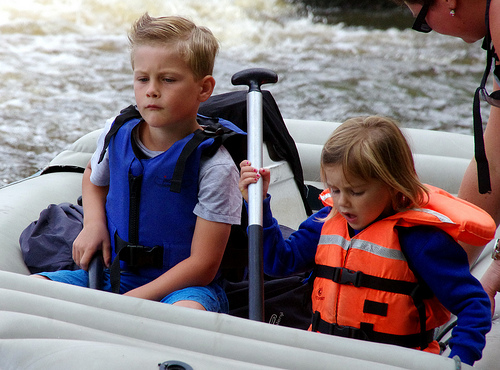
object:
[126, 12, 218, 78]
hair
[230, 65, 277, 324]
paddle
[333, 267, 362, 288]
clip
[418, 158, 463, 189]
ground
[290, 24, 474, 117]
waves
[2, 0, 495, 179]
river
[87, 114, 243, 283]
shirt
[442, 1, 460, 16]
ear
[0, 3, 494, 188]
water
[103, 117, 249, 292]
blue jacket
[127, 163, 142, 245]
zipper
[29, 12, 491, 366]
boy girl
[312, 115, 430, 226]
hair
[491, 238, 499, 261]
wristwatch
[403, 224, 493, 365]
blue sleeve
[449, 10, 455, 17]
earring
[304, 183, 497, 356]
life jacket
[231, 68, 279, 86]
handle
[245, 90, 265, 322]
pole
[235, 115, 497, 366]
girl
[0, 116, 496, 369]
raft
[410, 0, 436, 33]
glasses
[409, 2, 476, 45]
face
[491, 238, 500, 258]
face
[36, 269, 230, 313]
shorts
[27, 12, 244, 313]
boy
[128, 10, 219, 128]
head